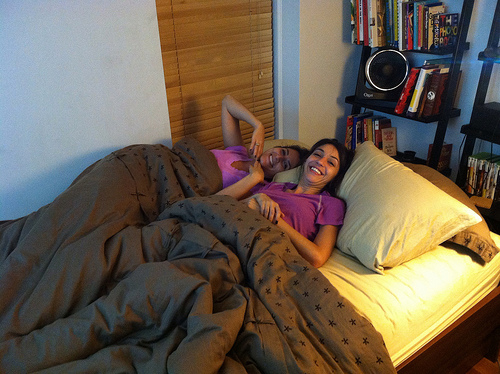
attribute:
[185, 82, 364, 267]
they — laying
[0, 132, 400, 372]
blanket — brown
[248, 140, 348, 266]
lady — smiling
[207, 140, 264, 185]
shirt — pink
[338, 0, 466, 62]
books — standing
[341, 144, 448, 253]
pillow — large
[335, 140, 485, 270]
pillow — large, brown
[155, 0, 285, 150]
blind — closed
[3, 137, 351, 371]
covers — dark brown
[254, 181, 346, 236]
shirt — purple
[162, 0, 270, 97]
blinds — brown, wooden, venetian